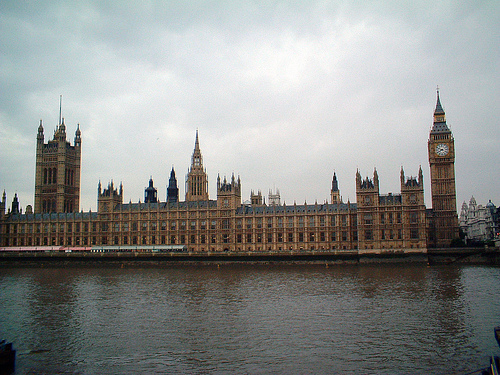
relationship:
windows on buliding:
[114, 218, 197, 239] [87, 194, 434, 277]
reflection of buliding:
[421, 263, 490, 345] [87, 194, 434, 277]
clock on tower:
[423, 140, 473, 165] [407, 99, 468, 194]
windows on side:
[114, 218, 197, 239] [87, 182, 224, 266]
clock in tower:
[423, 140, 473, 165] [407, 99, 468, 194]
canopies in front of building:
[1, 242, 187, 254] [1, 86, 464, 257]